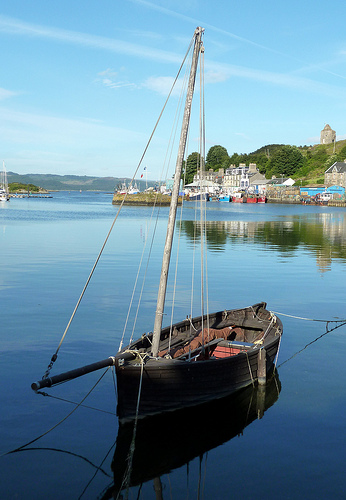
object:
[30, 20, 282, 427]
ship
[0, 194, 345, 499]
bay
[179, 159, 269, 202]
town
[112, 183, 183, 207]
island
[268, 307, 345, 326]
rope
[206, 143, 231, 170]
tree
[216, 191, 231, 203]
boat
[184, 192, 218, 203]
dock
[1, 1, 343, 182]
sky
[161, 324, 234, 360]
sail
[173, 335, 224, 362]
oar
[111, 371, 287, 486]
shadow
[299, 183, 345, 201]
building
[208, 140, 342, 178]
hill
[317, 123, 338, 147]
structure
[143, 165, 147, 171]
flag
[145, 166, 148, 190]
post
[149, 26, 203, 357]
mast